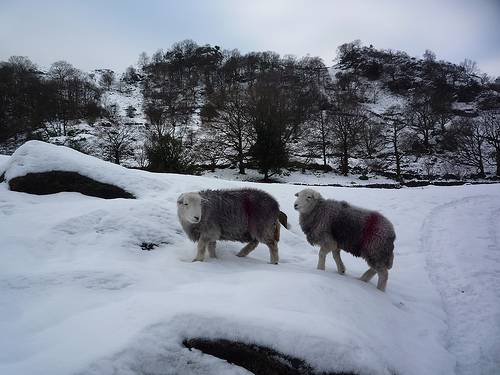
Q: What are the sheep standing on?
A: Snow.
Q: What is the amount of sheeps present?
A: Two.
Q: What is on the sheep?
A: Red mark.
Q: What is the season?
A: Winter.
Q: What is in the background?
A: Trees.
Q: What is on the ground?
A: Snow.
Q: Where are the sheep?
A: On hill.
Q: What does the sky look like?
A: Cloudy.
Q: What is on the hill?
A: Snow.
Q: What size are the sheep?
A: Adult.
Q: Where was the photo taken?
A: In a field.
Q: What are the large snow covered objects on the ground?
A: Rocks.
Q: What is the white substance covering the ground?
A: Snow.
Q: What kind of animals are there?
A: Sheep.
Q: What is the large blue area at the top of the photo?
A: The sky.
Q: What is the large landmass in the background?
A: A hill.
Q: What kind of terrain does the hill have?
A: Rocky.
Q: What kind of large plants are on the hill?
A: Trees.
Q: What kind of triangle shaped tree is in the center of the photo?
A: A pine tree.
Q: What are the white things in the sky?
A: Clouds.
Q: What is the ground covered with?
A: Snow.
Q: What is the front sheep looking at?
A: The back sheep.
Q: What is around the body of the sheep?
A: A reddish strip.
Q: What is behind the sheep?
A: Rows of trees.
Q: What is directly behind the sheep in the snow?
A: A large rock.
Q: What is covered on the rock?
A: Snow.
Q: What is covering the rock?
A: Snow.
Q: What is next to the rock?
A: Sheep.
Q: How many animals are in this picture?
A: 2.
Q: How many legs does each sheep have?
A: 4.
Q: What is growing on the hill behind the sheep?
A: Trees.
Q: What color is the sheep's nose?
A: Black.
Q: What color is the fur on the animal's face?
A: White.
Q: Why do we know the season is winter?
A: Snow.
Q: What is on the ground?
A: Snow.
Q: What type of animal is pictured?
A: Sheep.